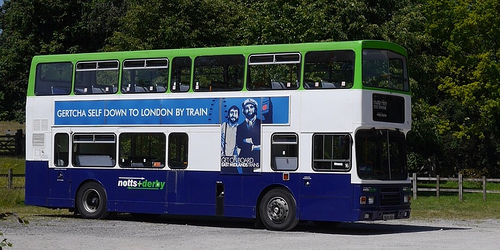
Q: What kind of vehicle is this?
A: Bus.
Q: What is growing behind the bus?
A: Trees.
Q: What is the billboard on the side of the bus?
A: Advertisement.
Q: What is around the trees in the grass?
A: Fence.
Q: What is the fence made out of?
A: Wood.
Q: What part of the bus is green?
A: Top.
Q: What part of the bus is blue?
A: Bottom.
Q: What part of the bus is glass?
A: Windows.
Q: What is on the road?
A: A bus.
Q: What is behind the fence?
A: Trees.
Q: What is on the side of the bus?
A: An advertisement.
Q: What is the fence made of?
A: Wood.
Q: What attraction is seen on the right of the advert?
A: Big ben.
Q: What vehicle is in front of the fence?
A: A tour bus.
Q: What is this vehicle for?
A: Guided tours.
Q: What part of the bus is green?
A: The top.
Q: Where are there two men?
A: Advert on the side of the bus.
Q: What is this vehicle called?
A: Bus.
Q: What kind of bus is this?
A: Tour.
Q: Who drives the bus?
A: Bus driver.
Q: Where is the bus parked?
A: Parking lot.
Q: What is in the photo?
A: A bus.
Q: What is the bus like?
A: Double decker.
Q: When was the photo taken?
A: Daytime.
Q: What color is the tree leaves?
A: Green.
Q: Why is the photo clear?
A: Its during the day.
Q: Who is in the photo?
A: Nobody.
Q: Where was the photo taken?
A: Near bus.